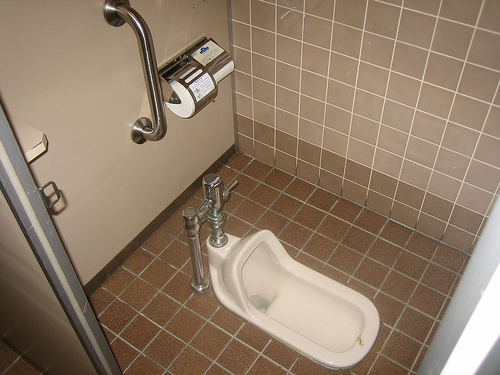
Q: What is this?
A: Washroom.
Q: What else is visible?
A: Toilet.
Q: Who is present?
A: No one.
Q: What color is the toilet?
A: White.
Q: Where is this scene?
A: Bathroom.